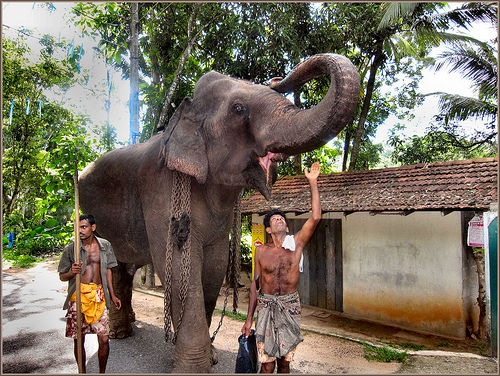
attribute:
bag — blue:
[232, 321, 258, 373]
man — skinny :
[223, 159, 323, 374]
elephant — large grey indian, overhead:
[77, 52, 361, 374]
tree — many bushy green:
[126, 10, 403, 162]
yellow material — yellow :
[69, 282, 105, 321]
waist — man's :
[70, 278, 102, 293]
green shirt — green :
[58, 234, 118, 309]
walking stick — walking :
[70, 174, 83, 374]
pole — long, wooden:
[69, 157, 86, 374]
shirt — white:
[283, 233, 308, 275]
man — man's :
[227, 157, 338, 373]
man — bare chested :
[240, 160, 320, 372]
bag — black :
[234, 329, 259, 372]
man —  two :
[57, 212, 122, 373]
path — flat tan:
[1, 249, 498, 372]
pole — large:
[66, 189, 86, 369]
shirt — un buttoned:
[64, 233, 118, 298]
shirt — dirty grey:
[248, 287, 303, 362]